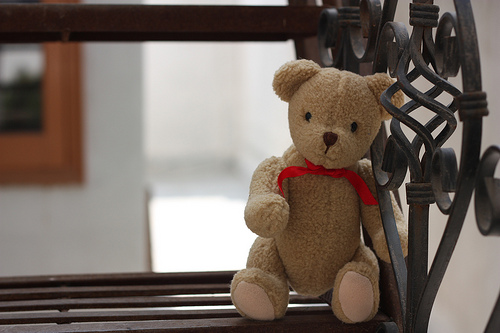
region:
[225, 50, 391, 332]
teddy bear with red ribbon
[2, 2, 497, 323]
teddy bear sitting on wrought iron bench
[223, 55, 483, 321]
teddy bear leaning on metal arm rest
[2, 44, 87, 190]
picture in brown frame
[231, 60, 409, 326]
brown teddy bear with red ribbon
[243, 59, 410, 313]
stuffed bear with red ribbon collar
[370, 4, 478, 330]
decorative black iron bench arm rest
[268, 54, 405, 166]
a stuffed brown teddy bear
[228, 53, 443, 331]
stuffed bear sitting on bench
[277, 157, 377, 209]
red ribbon tied to stuffed toy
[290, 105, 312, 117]
Bear has black eye.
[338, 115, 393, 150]
Bear has black eye.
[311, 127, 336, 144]
Bear has brown nose.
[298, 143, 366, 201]
Bear has ribbon around neck.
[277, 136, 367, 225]
Bow around bear's neck is red.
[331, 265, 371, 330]
Tan pad on bear's foot.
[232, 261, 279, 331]
Tan pad on bear's foot.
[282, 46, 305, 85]
Bear has brown ear.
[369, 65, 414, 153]
Bear has brown ear.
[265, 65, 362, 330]
Teddy bear is sitting on bench.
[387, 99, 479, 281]
the metal is iron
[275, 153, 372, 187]
the bow is red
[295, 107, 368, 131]
the eyes are black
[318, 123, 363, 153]
the nose is black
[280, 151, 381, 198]
bow around the neck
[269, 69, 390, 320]
the bear is tan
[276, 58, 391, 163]
ears on the bear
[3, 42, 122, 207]
frame is on the wall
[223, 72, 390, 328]
the bear on bench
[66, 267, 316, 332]
the bench is iron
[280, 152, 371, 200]
a red ribbon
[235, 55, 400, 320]
A Teddy Bear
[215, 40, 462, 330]
teddy bear sitting on a bench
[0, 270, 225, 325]
a brown sitting bench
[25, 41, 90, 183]
wooden, brown picture frame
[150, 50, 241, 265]
sunlight in the hallway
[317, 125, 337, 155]
teddy bear's brown nose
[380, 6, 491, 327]
side of bench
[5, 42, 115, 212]
picture hanging on the wall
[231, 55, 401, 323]
teddy bear wearing red ribbon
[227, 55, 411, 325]
brown teddy bear sitting on a bench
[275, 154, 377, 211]
red ribbon around bear's neck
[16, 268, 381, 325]
wooden seat of bench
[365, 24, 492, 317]
iron scrollwork on bench arm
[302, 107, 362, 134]
black button eyes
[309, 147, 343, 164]
stitched line of a mouth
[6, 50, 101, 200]
wooden picture frame hanging on wall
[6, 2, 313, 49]
wooden bench back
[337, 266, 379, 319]
lighter colored foot pad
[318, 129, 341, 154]
black round nose